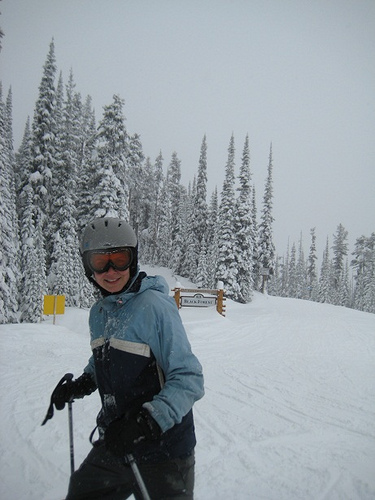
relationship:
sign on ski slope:
[171, 287, 225, 314] [152, 265, 347, 462]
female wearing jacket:
[41, 216, 206, 498] [74, 267, 203, 432]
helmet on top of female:
[80, 215, 136, 247] [41, 216, 206, 498]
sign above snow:
[31, 283, 85, 337] [3, 325, 99, 371]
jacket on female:
[82, 267, 206, 436] [41, 216, 206, 498]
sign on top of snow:
[171, 287, 225, 314] [223, 319, 305, 346]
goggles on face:
[83, 249, 132, 271] [84, 244, 135, 292]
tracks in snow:
[234, 363, 331, 429] [108, 233, 353, 485]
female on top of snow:
[41, 216, 206, 498] [1, 258, 374, 499]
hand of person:
[99, 410, 158, 461] [21, 207, 232, 498]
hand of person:
[52, 372, 85, 412] [21, 207, 232, 498]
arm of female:
[143, 302, 205, 411] [41, 216, 206, 498]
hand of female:
[38, 364, 99, 425] [41, 216, 206, 498]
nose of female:
[103, 268, 122, 283] [41, 216, 206, 498]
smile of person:
[98, 274, 129, 291] [21, 207, 232, 498]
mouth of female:
[101, 275, 132, 290] [41, 216, 206, 498]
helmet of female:
[80, 215, 138, 287] [41, 216, 206, 498]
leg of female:
[62, 443, 131, 499] [41, 216, 206, 498]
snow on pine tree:
[217, 183, 266, 311] [257, 144, 278, 294]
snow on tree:
[1, 41, 373, 496] [351, 227, 373, 314]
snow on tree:
[1, 41, 373, 496] [280, 234, 291, 297]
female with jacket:
[41, 201, 211, 498] [64, 272, 209, 432]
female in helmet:
[41, 216, 206, 498] [62, 199, 148, 248]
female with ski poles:
[41, 216, 206, 498] [31, 379, 176, 499]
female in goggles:
[41, 216, 206, 498] [83, 249, 133, 271]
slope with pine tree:
[278, 297, 341, 323] [24, 36, 65, 244]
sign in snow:
[40, 293, 66, 315] [1, 258, 374, 499]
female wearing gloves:
[41, 216, 206, 498] [50, 375, 157, 458]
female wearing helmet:
[41, 216, 206, 498] [78, 216, 139, 259]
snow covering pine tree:
[1, 41, 373, 496] [0, 92, 25, 320]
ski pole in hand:
[60, 365, 80, 493] [107, 324, 284, 495]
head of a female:
[78, 214, 144, 292] [41, 216, 206, 498]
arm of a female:
[143, 302, 205, 411] [41, 216, 206, 498]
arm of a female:
[77, 352, 98, 396] [41, 216, 206, 498]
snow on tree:
[248, 224, 258, 253] [221, 110, 313, 303]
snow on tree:
[229, 278, 244, 295] [212, 126, 253, 306]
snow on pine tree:
[191, 142, 219, 258] [185, 130, 211, 282]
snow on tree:
[153, 227, 169, 243] [114, 151, 226, 299]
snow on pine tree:
[307, 252, 316, 264] [304, 225, 317, 298]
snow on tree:
[327, 220, 352, 305] [328, 224, 347, 298]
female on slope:
[41, 216, 206, 498] [0, 296, 372, 496]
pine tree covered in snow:
[257, 137, 282, 298] [28, 169, 48, 186]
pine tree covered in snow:
[185, 130, 211, 282] [28, 169, 48, 186]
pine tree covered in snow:
[77, 88, 133, 224] [28, 169, 48, 186]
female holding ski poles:
[41, 216, 206, 498] [56, 366, 152, 498]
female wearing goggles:
[41, 216, 206, 498] [79, 247, 119, 278]